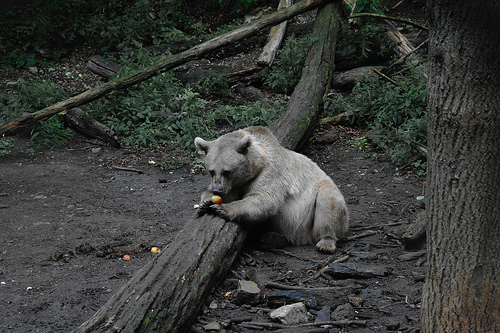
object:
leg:
[312, 187, 349, 253]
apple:
[211, 191, 221, 203]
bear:
[179, 110, 340, 259]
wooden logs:
[0, 0, 500, 332]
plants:
[119, 84, 273, 128]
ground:
[0, 0, 427, 332]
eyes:
[220, 167, 233, 181]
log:
[63, 212, 250, 326]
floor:
[10, 177, 136, 265]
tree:
[245, 9, 412, 141]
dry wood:
[95, 0, 313, 92]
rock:
[267, 300, 314, 325]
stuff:
[233, 274, 321, 320]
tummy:
[275, 191, 316, 245]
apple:
[119, 249, 131, 260]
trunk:
[137, 212, 237, 275]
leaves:
[341, 134, 368, 149]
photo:
[7, 5, 493, 330]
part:
[359, 211, 402, 261]